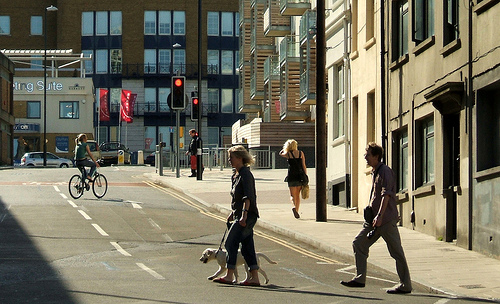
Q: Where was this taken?
A: City.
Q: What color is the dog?
A: White.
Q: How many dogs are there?
A: 1.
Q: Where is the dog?
A: By the woman.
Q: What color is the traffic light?
A: Red.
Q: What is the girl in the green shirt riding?
A: Bicycle.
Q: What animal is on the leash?
A: A dog.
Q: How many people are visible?
A: 5.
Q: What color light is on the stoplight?
A: Red.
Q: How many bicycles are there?
A: 1.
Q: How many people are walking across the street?
A: 2.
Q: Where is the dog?
A: To the right of the lady.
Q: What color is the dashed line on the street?
A: White.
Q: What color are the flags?
A: Red.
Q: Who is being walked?
A: The dog.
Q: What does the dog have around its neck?
A: Leash.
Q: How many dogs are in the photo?
A: One.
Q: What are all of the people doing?
A: Walking.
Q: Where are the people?
A: In a city.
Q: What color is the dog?
A: White.